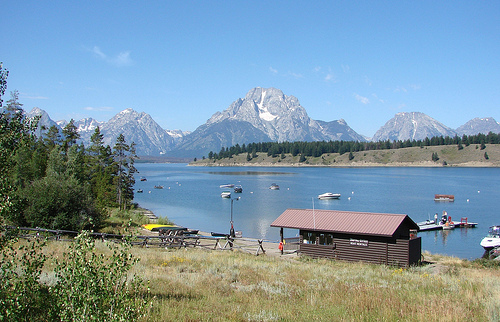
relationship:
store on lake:
[276, 203, 423, 270] [133, 160, 499, 255]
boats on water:
[138, 172, 465, 216] [133, 160, 499, 255]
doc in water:
[417, 214, 482, 234] [133, 160, 499, 255]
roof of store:
[268, 201, 423, 241] [276, 203, 423, 270]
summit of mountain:
[235, 86, 302, 112] [191, 82, 359, 159]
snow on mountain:
[253, 86, 282, 126] [191, 82, 359, 159]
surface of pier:
[417, 214, 482, 234] [405, 218, 477, 239]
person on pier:
[442, 213, 450, 224] [405, 218, 477, 239]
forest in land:
[212, 135, 500, 160] [196, 145, 499, 169]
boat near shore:
[479, 225, 500, 247] [423, 245, 500, 277]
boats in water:
[138, 172, 465, 216] [133, 160, 499, 255]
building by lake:
[276, 203, 423, 270] [133, 160, 499, 255]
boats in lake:
[138, 172, 465, 216] [133, 160, 499, 255]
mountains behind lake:
[1, 86, 500, 152] [133, 160, 499, 255]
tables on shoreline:
[145, 223, 210, 255] [177, 222, 290, 252]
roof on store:
[268, 201, 423, 241] [276, 203, 423, 270]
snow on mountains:
[253, 86, 282, 126] [191, 82, 359, 159]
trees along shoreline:
[35, 118, 144, 206] [126, 192, 279, 244]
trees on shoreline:
[35, 118, 144, 206] [126, 192, 279, 244]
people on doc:
[442, 213, 450, 224] [417, 214, 482, 234]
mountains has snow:
[1, 86, 500, 152] [253, 86, 282, 126]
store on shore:
[276, 203, 423, 270] [264, 237, 472, 274]